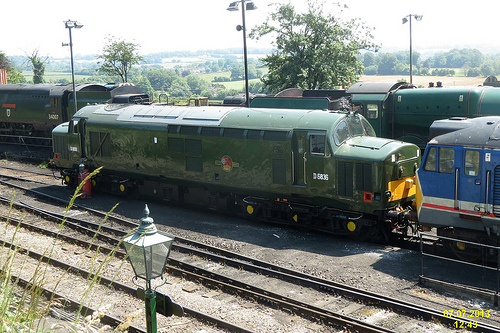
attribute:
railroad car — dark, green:
[62, 110, 410, 236]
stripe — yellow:
[383, 174, 415, 196]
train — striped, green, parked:
[60, 95, 418, 242]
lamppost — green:
[139, 285, 160, 329]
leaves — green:
[265, 11, 362, 85]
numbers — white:
[309, 173, 331, 182]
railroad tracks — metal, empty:
[7, 261, 188, 332]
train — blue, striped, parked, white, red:
[422, 132, 498, 216]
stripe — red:
[425, 196, 496, 226]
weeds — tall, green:
[0, 188, 125, 329]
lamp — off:
[115, 203, 176, 278]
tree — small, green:
[90, 43, 141, 79]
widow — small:
[436, 146, 455, 174]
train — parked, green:
[3, 81, 130, 139]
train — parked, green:
[370, 83, 499, 137]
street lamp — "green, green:
[131, 212, 167, 332]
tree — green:
[254, 5, 360, 87]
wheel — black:
[439, 226, 487, 263]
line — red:
[420, 198, 499, 217]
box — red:
[70, 167, 93, 199]